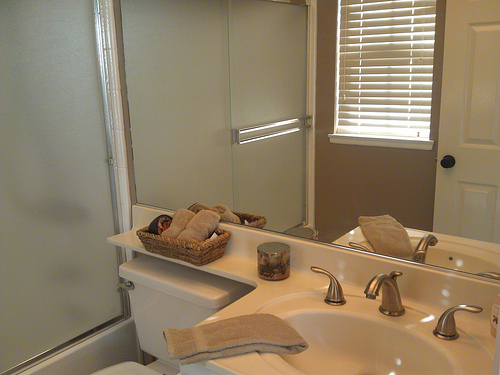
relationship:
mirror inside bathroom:
[119, 1, 499, 282] [1, 0, 499, 374]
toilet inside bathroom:
[90, 257, 249, 375] [1, 0, 499, 374]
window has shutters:
[336, 0, 437, 141] [336, 0, 435, 136]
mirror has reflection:
[119, 1, 499, 282] [315, 0, 447, 243]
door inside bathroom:
[431, 0, 499, 243] [1, 0, 499, 374]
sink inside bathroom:
[251, 290, 494, 375] [1, 0, 499, 374]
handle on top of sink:
[309, 265, 347, 308] [251, 290, 494, 375]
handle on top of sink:
[432, 304, 485, 341] [251, 290, 494, 375]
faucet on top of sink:
[364, 270, 406, 318] [251, 290, 494, 375]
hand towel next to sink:
[161, 313, 308, 365] [251, 290, 494, 375]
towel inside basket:
[159, 208, 197, 238] [136, 225, 233, 266]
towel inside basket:
[178, 210, 221, 241] [136, 225, 233, 266]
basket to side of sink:
[136, 225, 233, 266] [251, 290, 494, 375]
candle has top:
[258, 241, 292, 281] [256, 241, 288, 254]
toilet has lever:
[90, 257, 249, 375] [116, 280, 134, 293]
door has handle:
[431, 0, 499, 243] [309, 265, 347, 308]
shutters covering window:
[336, 0, 435, 136] [336, 0, 437, 141]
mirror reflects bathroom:
[119, 1, 499, 282] [1, 0, 499, 374]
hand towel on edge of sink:
[161, 313, 308, 365] [251, 290, 494, 375]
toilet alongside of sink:
[90, 257, 249, 375] [251, 290, 494, 375]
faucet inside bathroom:
[364, 270, 406, 318] [1, 0, 499, 374]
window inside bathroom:
[336, 0, 437, 141] [1, 0, 499, 374]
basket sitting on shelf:
[136, 225, 233, 266] [107, 205, 268, 287]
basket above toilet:
[136, 225, 233, 266] [90, 257, 249, 375]